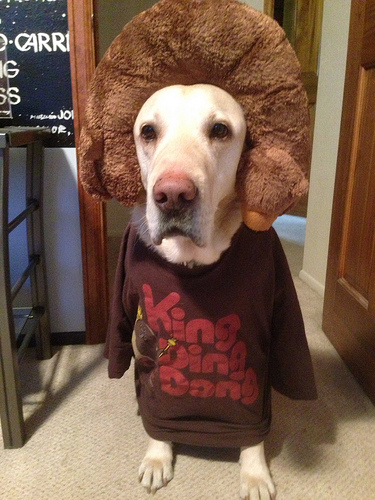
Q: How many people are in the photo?
A: 0.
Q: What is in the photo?
A: Dog.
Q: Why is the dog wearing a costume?
A: Funny.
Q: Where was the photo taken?
A: House.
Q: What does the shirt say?
A: King ding dong.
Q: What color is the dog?
A: Blonde.